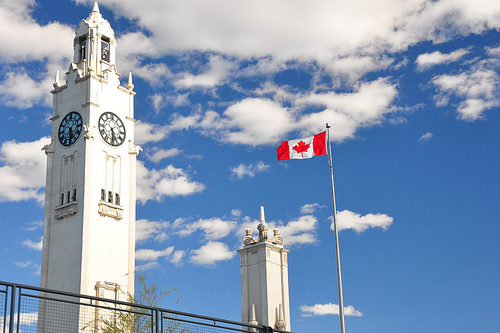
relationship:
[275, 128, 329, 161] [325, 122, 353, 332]
flag on pole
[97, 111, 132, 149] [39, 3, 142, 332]
clock on building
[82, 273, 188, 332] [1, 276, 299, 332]
tree behind fence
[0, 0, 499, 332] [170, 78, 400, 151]
sky has clouds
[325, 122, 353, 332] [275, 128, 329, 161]
pole with flag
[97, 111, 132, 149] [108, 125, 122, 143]
clock showing 5:30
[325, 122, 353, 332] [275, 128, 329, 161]
pole has flag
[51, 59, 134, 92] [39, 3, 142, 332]
parapets over building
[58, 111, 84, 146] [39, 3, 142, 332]
clock on building